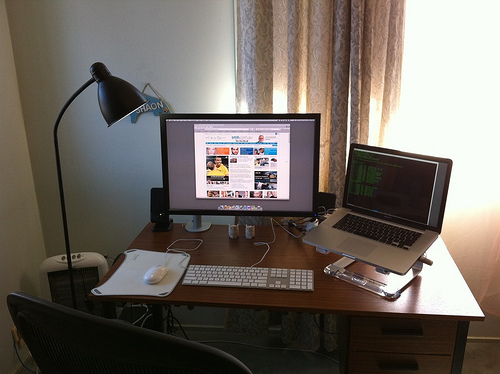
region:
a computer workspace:
[6, 32, 496, 363]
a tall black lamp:
[48, 65, 146, 306]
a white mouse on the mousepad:
[145, 261, 166, 282]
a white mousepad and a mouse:
[100, 245, 188, 296]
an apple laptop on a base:
[306, 151, 447, 271]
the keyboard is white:
[185, 261, 311, 291]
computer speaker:
[148, 188, 168, 230]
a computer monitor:
[161, 115, 316, 215]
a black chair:
[7, 295, 244, 368]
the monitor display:
[167, 120, 313, 210]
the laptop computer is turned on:
[297, 139, 454, 277]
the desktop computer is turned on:
[146, 111, 321, 294]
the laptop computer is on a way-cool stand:
[313, 247, 436, 301]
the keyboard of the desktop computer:
[176, 258, 316, 296]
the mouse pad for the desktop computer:
[87, 241, 193, 303]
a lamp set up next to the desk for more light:
[48, 57, 150, 314]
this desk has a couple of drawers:
[341, 304, 468, 372]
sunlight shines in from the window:
[391, 76, 496, 212]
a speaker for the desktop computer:
[146, 183, 176, 235]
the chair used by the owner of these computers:
[4, 285, 255, 372]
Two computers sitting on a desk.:
[27, 27, 468, 340]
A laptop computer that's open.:
[305, 130, 459, 284]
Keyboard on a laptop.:
[326, 204, 422, 254]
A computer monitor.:
[158, 109, 320, 220]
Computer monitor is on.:
[157, 105, 322, 220]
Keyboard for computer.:
[181, 249, 317, 294]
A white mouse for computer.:
[135, 258, 170, 291]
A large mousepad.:
[92, 235, 189, 303]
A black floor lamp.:
[24, 55, 149, 299]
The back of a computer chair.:
[6, 281, 260, 367]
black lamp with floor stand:
[51, 60, 146, 309]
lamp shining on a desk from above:
[53, 60, 145, 311]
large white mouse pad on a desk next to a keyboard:
[88, 247, 191, 297]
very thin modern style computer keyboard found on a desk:
[181, 261, 316, 291]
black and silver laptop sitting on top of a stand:
[303, 143, 454, 275]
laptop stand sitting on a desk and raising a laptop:
[321, 251, 432, 300]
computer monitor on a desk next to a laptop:
[159, 111, 320, 217]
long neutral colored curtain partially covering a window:
[225, 0, 408, 353]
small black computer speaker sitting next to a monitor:
[147, 185, 172, 231]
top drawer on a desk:
[343, 314, 460, 356]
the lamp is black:
[37, 53, 187, 178]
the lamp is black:
[68, 46, 148, 131]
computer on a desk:
[98, 93, 465, 344]